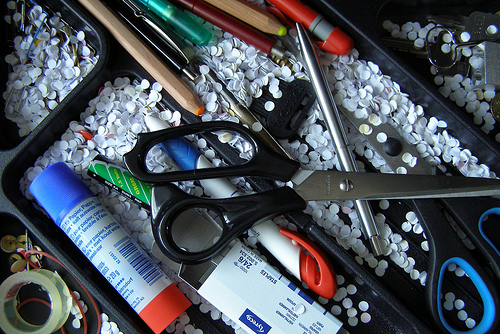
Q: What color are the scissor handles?
A: Black.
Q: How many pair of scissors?
A: Two.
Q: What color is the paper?
A: White.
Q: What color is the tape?
A: Clear.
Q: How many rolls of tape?
A: One.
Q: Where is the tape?
A: Left hand corner.